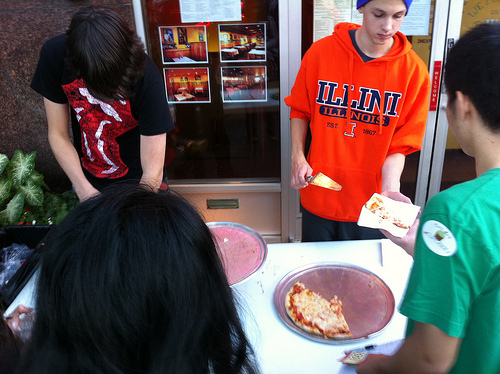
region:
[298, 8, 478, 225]
a door on the building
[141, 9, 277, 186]
a window on the building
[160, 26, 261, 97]
pictures hanging on the window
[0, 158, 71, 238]
a plant in front of the building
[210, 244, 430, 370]
a white table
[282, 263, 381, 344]
a pizza on a platter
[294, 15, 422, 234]
a man in an orange sweater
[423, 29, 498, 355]
a man in a green shirt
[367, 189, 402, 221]
a piece of pizza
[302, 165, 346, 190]
a spatula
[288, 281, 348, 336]
some pieces of cheese pizza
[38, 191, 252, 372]
the head of the woman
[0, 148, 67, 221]
a green plant to the left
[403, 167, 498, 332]
he is wearing a green t-shirt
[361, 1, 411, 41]
the head of the boy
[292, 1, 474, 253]
he is giving a piece of pizza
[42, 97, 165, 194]
the two arms of the boy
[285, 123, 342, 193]
he is holdinng a spatula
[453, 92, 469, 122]
one ear of the boy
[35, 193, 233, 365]
this hair is black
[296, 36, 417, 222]
guy wearing a orange sweatshirt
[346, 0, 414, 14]
guy wearing a blue hat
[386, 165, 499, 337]
guy wearing a green tee shirt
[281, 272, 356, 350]
pizza on a pan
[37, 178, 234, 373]
person with black hair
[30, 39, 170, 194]
guy wearing a black tee shirt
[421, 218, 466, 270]
sticker on a tee shirt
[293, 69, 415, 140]
Blue letters on the sweatshirt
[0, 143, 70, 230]
plant in the pot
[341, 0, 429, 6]
boy has blue hat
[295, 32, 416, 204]
boy has orange hoodie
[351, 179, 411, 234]
pizza on white napkin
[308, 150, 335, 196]
boy is holding spatula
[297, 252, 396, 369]
pizza on silver tray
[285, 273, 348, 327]
yellow cheese on pizza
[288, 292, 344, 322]
orange sauce on pizza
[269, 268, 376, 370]
tray on white table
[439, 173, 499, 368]
person has green shirt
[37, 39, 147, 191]
person has black shirt